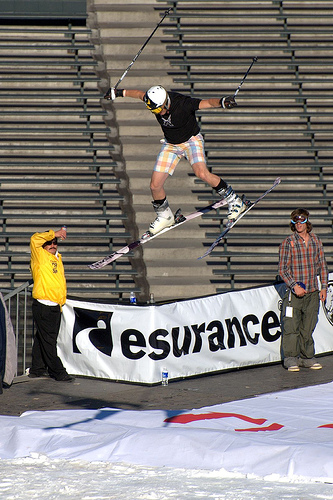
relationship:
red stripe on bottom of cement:
[166, 412, 269, 426] [10, 387, 254, 404]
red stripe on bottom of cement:
[163, 412, 284, 432] [1, 350, 332, 415]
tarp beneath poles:
[114, 376, 328, 493] [104, 85, 248, 236]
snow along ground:
[0, 452, 333, 500] [4, 386, 326, 467]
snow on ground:
[14, 451, 264, 498] [10, 384, 331, 492]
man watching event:
[16, 192, 91, 343] [9, 8, 322, 494]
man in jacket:
[16, 192, 91, 343] [31, 251, 64, 304]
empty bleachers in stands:
[0, 12, 126, 333] [4, 8, 119, 236]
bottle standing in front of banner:
[122, 350, 199, 425] [56, 272, 333, 383]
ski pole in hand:
[229, 46, 268, 91] [210, 79, 246, 118]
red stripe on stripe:
[163, 412, 284, 432] [317, 421, 331, 429]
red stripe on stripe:
[163, 412, 284, 432] [233, 422, 283, 431]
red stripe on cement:
[163, 412, 284, 432] [188, 388, 269, 444]